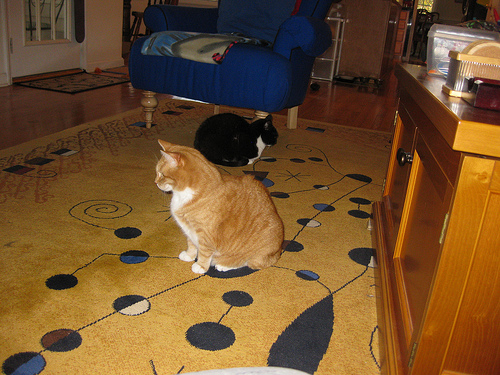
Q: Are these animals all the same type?
A: Yes, all the animals are cats.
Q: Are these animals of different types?
A: No, all the animals are cats.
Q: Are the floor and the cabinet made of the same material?
A: Yes, both the floor and the cabinet are made of wood.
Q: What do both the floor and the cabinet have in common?
A: The material, both the floor and the cabinet are wooden.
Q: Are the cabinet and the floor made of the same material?
A: Yes, both the cabinet and the floor are made of wood.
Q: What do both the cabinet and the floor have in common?
A: The material, both the cabinet and the floor are wooden.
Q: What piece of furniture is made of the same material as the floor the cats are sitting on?
A: The cabinet is made of the same material as the floor.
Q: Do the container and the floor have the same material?
A: No, the container is made of plastic and the floor is made of wood.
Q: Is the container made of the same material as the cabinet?
A: No, the container is made of plastic and the cabinet is made of wood.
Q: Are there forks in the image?
A: No, there are no forks.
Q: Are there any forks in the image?
A: No, there are no forks.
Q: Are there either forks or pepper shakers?
A: No, there are no forks or pepper shakers.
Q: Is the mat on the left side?
A: Yes, the mat is on the left of the image.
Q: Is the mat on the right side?
A: No, the mat is on the left of the image.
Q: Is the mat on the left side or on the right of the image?
A: The mat is on the left of the image.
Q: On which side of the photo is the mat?
A: The mat is on the left of the image.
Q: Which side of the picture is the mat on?
A: The mat is on the left of the image.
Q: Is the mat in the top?
A: Yes, the mat is in the top of the image.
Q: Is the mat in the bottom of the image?
A: No, the mat is in the top of the image.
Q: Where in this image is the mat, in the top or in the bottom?
A: The mat is in the top of the image.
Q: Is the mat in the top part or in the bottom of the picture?
A: The mat is in the top of the image.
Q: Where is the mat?
A: The mat is on the floor.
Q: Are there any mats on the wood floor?
A: Yes, there is a mat on the floor.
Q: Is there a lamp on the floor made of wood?
A: No, there is a mat on the floor.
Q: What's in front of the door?
A: The mat is in front of the door.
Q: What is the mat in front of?
A: The mat is in front of the door.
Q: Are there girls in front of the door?
A: No, there is a mat in front of the door.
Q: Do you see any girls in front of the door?
A: No, there is a mat in front of the door.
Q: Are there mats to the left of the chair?
A: Yes, there is a mat to the left of the chair.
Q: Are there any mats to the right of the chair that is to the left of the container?
A: No, the mat is to the left of the chair.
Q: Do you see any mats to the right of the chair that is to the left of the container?
A: No, the mat is to the left of the chair.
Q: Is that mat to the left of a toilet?
A: No, the mat is to the left of the chair.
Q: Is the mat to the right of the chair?
A: No, the mat is to the left of the chair.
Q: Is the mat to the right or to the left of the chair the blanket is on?
A: The mat is to the left of the chair.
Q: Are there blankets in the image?
A: Yes, there is a blanket.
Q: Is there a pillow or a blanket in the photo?
A: Yes, there is a blanket.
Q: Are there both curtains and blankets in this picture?
A: No, there is a blanket but no curtains.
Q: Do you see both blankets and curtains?
A: No, there is a blanket but no curtains.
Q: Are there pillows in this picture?
A: No, there are no pillows.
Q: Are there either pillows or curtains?
A: No, there are no pillows or curtains.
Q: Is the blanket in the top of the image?
A: Yes, the blanket is in the top of the image.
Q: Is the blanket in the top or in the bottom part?
A: The blanket is in the top of the image.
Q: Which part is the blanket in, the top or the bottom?
A: The blanket is in the top of the image.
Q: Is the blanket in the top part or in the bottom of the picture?
A: The blanket is in the top of the image.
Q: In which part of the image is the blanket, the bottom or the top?
A: The blanket is in the top of the image.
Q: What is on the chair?
A: The blanket is on the chair.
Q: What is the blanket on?
A: The blanket is on the chair.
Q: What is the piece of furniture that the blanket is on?
A: The piece of furniture is a chair.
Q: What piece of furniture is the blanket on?
A: The blanket is on the chair.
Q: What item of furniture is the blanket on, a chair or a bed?
A: The blanket is on a chair.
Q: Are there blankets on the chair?
A: Yes, there is a blanket on the chair.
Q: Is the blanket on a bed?
A: No, the blanket is on the chair.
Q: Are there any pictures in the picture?
A: No, there are no pictures.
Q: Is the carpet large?
A: Yes, the carpet is large.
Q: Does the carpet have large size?
A: Yes, the carpet is large.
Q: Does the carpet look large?
A: Yes, the carpet is large.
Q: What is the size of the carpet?
A: The carpet is large.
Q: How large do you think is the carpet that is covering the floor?
A: The carpet is large.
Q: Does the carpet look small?
A: No, the carpet is large.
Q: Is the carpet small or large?
A: The carpet is large.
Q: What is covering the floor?
A: The carpet is covering the floor.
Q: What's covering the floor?
A: The carpet is covering the floor.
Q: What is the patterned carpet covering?
A: The carpet is covering the floor.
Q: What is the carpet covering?
A: The carpet is covering the floor.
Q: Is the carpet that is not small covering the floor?
A: Yes, the carpet is covering the floor.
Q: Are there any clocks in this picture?
A: No, there are no clocks.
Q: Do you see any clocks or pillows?
A: No, there are no clocks or pillows.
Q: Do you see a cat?
A: Yes, there is a cat.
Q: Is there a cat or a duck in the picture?
A: Yes, there is a cat.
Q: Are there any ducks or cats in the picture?
A: Yes, there is a cat.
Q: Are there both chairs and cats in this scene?
A: Yes, there are both a cat and a chair.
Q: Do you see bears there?
A: No, there are no bears.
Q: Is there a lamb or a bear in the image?
A: No, there are no bears or lambs.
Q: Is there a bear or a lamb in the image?
A: No, there are no bears or lambs.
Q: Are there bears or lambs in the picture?
A: No, there are no bears or lambs.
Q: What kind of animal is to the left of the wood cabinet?
A: The animal is a cat.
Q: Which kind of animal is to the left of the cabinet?
A: The animal is a cat.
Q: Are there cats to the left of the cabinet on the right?
A: Yes, there is a cat to the left of the cabinet.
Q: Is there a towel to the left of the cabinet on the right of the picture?
A: No, there is a cat to the left of the cabinet.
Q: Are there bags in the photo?
A: No, there are no bags.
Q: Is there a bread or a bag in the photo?
A: No, there are no bags or breads.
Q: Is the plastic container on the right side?
A: Yes, the container is on the right of the image.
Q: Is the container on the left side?
A: No, the container is on the right of the image.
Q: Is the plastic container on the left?
A: No, the container is on the right of the image.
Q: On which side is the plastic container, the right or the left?
A: The container is on the right of the image.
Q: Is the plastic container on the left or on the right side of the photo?
A: The container is on the right of the image.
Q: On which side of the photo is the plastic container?
A: The container is on the right of the image.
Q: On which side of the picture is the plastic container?
A: The container is on the right of the image.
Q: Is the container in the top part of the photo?
A: Yes, the container is in the top of the image.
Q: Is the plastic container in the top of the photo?
A: Yes, the container is in the top of the image.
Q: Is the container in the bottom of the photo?
A: No, the container is in the top of the image.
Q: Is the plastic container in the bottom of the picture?
A: No, the container is in the top of the image.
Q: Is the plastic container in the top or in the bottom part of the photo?
A: The container is in the top of the image.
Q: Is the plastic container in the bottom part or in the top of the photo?
A: The container is in the top of the image.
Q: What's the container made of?
A: The container is made of plastic.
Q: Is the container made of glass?
A: No, the container is made of plastic.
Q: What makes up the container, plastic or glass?
A: The container is made of plastic.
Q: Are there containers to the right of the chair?
A: Yes, there is a container to the right of the chair.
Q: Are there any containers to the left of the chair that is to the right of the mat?
A: No, the container is to the right of the chair.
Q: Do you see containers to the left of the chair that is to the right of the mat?
A: No, the container is to the right of the chair.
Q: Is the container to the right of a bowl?
A: No, the container is to the right of the chair.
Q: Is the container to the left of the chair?
A: No, the container is to the right of the chair.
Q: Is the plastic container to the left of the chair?
A: No, the container is to the right of the chair.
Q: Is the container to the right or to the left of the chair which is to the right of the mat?
A: The container is to the right of the chair.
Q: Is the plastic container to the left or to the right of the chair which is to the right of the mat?
A: The container is to the right of the chair.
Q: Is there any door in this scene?
A: Yes, there is a door.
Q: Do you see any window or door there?
A: Yes, there is a door.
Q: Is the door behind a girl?
A: No, the door is behind the mat.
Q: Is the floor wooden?
A: Yes, the floor is wooden.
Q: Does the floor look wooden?
A: Yes, the floor is wooden.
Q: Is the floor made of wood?
A: Yes, the floor is made of wood.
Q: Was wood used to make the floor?
A: Yes, the floor is made of wood.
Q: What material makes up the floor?
A: The floor is made of wood.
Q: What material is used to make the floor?
A: The floor is made of wood.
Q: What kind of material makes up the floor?
A: The floor is made of wood.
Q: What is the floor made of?
A: The floor is made of wood.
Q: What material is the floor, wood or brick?
A: The floor is made of wood.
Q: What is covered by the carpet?
A: The floor is covered by the carpet.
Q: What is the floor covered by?
A: The floor is covered by the carpet.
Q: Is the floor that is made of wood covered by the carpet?
A: Yes, the floor is covered by the carpet.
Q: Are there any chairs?
A: Yes, there is a chair.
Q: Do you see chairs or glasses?
A: Yes, there is a chair.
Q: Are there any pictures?
A: No, there are no pictures.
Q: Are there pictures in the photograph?
A: No, there are no pictures.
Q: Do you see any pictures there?
A: No, there are no pictures.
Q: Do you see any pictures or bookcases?
A: No, there are no pictures or bookcases.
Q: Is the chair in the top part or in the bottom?
A: The chair is in the top of the image.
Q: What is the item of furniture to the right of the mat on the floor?
A: The piece of furniture is a chair.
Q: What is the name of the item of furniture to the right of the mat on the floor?
A: The piece of furniture is a chair.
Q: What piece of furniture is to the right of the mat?
A: The piece of furniture is a chair.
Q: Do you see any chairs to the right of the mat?
A: Yes, there is a chair to the right of the mat.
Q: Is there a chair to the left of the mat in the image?
A: No, the chair is to the right of the mat.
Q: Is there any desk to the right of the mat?
A: No, there is a chair to the right of the mat.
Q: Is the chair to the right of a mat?
A: Yes, the chair is to the right of a mat.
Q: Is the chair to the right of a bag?
A: No, the chair is to the right of a mat.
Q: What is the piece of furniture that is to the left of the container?
A: The piece of furniture is a chair.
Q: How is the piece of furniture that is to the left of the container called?
A: The piece of furniture is a chair.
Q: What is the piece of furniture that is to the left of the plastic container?
A: The piece of furniture is a chair.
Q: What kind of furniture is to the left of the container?
A: The piece of furniture is a chair.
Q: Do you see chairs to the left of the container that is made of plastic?
A: Yes, there is a chair to the left of the container.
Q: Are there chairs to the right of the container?
A: No, the chair is to the left of the container.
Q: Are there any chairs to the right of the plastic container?
A: No, the chair is to the left of the container.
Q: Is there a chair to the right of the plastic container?
A: No, the chair is to the left of the container.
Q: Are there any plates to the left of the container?
A: No, there is a chair to the left of the container.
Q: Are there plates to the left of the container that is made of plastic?
A: No, there is a chair to the left of the container.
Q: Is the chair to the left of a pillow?
A: No, the chair is to the left of a container.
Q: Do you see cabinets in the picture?
A: Yes, there is a cabinet.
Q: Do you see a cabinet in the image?
A: Yes, there is a cabinet.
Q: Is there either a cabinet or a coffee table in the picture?
A: Yes, there is a cabinet.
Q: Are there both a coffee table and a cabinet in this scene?
A: No, there is a cabinet but no coffee tables.